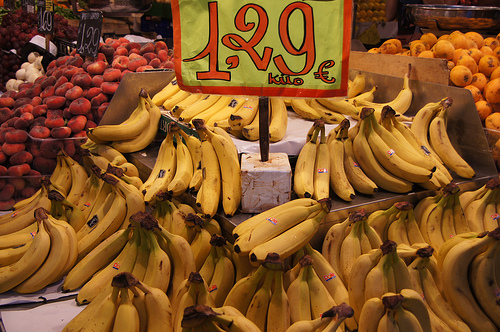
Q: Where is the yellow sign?
A: Middle of the bananas.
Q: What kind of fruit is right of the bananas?
A: Oranges.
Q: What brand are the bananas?
A: Dole.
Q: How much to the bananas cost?
A: 1.29 Euros per kilo.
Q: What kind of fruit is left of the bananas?
A: Apricots.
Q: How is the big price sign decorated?
A: Yellow sign with red borders.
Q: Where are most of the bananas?
A: Bottom row.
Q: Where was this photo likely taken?
A: Outdoor market.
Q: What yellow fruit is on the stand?
A: Bananas.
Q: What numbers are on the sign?
A: 129.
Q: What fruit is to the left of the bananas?
A: Kumquats.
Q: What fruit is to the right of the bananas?
A: Apricots.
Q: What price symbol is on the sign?
A: Euro.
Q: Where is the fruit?
A: Outdoor produce market.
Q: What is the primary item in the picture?
A: Bananas.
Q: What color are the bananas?
A: Yellow.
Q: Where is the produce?
A: At a mart.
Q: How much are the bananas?
A: $1.29 per kilo.